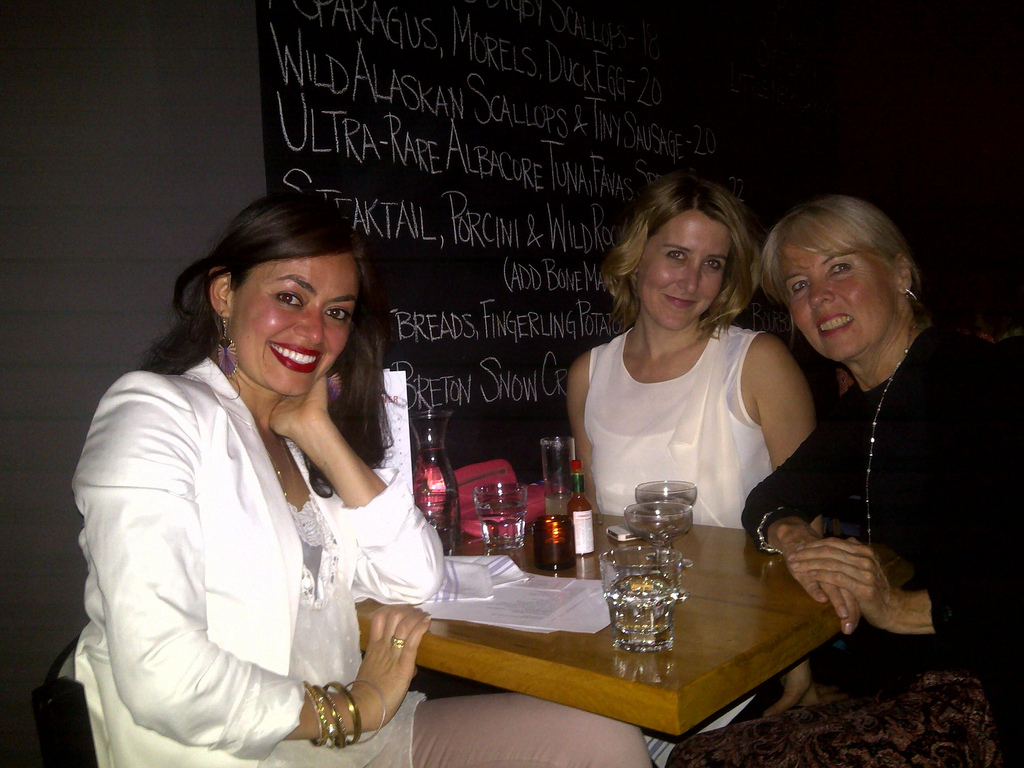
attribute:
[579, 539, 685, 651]
glass — clear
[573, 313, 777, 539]
shirt — white, sleeveless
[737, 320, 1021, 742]
sweater — black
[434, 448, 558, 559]
purse — pink